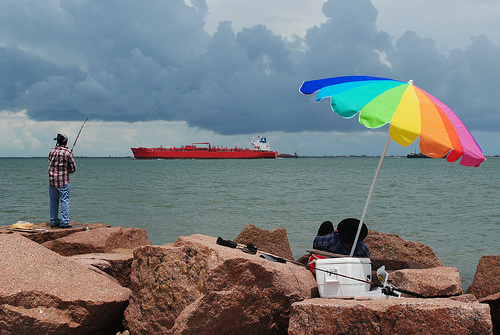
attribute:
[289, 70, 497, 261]
umbrella — multi-colored, bright, rainbow, multicolored, striped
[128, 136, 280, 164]
ship — long, red, large, cargo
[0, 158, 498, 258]
water — calm, blue, dark, large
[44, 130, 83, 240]
man — standing, fishing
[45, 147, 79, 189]
shirt — plaid, checkered, long sleeved, red, white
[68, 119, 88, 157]
pole — white, long, colored, black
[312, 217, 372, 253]
man — laying, lying, resting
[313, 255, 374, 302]
cooler — white, plastic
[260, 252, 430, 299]
pole — resting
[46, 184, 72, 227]
jeans — blue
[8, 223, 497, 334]
rocks — ragged, brown, large, red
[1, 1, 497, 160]
sky — cloudy, gray, dark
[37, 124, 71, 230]
person — fishing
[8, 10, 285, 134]
clouds — blue, dark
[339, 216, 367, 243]
cap — black